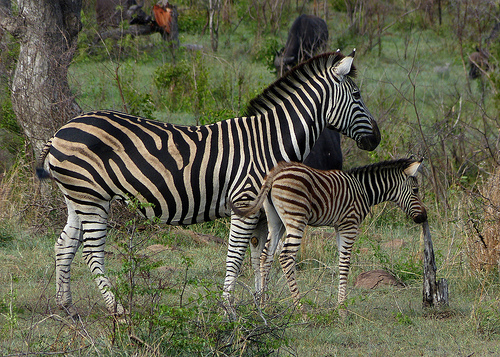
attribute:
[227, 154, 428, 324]
zebra — young, striped, black, white, baby, small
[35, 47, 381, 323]
zebra — large, tall, adult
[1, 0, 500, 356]
area — green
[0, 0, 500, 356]
branches — dry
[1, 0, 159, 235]
tree — standing, curved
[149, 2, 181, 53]
trunk — broken, gray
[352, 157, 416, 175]
mane — short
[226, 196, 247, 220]
hair — dark, black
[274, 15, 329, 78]
buffalo — grazing, black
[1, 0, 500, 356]
greenery — scraggly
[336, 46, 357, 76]
ear — white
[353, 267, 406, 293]
rock — large